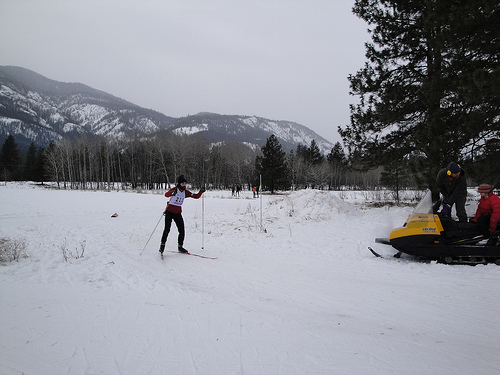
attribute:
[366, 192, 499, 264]
snowmobile — yellow, black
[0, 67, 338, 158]
mountain — snowy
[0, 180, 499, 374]
snow — white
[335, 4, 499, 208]
tree — pine, dark, green, evergreen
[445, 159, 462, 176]
earmuffs — yellow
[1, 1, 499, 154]
sky — cloudy, gray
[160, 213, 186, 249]
pants — black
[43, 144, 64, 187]
tree — leafless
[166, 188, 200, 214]
sweater — red